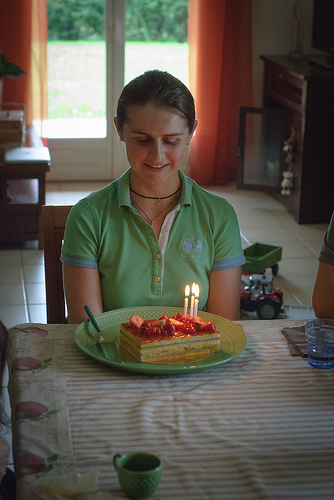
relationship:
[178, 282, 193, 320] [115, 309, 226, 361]
candle on cake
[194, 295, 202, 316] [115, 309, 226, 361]
candle on cake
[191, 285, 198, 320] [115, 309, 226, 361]
candle on cake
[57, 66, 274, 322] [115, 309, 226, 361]
woman enjoying cake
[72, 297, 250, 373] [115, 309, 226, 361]
plate with cake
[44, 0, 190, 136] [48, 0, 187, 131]
backyard behind glass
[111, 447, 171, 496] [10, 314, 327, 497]
coffee cup on table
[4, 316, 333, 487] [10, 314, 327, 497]
tablecloth on table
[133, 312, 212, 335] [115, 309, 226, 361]
strawberries on cake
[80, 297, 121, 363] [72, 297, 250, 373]
cake cutter on plate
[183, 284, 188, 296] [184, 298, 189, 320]
flame on candle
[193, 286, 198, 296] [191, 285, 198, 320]
flame on candle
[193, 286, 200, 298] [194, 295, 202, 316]
flame on candle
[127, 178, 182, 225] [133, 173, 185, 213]
necklaces around neck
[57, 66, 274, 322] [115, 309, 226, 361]
woman eats cake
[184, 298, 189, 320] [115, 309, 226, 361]
candle on cake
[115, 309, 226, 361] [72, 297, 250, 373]
cake on plate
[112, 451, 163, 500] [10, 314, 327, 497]
coffee cup on table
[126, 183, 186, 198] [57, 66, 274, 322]
nacklace on woman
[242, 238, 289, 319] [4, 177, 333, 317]
toys on floor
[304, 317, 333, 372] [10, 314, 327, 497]
glass on table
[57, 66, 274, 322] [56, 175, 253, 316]
woman wearing shirt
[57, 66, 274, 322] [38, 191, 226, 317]
woman in chair